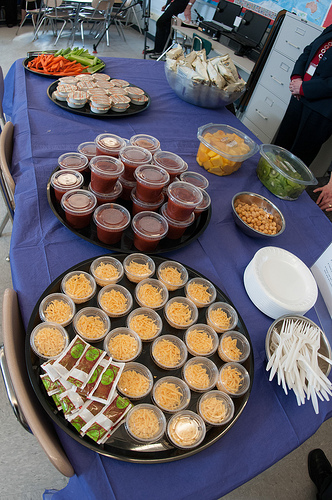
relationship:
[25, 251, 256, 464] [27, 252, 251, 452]
tray has cheese cups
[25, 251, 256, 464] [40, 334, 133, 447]
tray has sauce packets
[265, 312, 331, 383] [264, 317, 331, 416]
bowl has forks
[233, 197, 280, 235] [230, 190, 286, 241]
chickpeas are in a bowl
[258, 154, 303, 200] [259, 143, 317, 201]
kiwi in a plastic dish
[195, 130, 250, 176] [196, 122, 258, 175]
mangoes are in a plastic dish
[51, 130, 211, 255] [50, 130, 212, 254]
sauce in small dishes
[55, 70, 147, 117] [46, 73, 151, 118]
peanut butter cups are on a tray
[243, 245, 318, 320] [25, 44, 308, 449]
plates are for food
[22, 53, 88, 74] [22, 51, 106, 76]
carrots are on a plate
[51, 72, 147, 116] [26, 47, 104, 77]
dip for dipping veggies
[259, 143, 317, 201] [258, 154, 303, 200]
plastic dish has kiwi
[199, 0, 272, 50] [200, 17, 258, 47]
computers have keyboards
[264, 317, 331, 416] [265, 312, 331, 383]
forks are in a bowl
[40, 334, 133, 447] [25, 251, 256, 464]
sauce packets are on a tray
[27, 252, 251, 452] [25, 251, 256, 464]
cheese cups are on a tray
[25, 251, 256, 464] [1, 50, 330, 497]
tray on a table cover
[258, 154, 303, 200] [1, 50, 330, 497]
kiwi on table cover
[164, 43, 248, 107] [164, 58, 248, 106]
bags are stacked in a bowl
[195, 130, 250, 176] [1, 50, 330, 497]
pineapple on table cover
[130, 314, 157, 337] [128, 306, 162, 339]
cheese in a container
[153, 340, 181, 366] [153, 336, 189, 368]
cheese in a container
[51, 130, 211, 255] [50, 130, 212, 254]
sauce in containers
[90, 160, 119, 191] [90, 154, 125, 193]
salsa in a container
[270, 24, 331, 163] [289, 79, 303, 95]
person has hands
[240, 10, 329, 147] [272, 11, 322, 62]
cabinet has a drawer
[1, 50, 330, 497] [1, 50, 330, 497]
table cover on a table cover